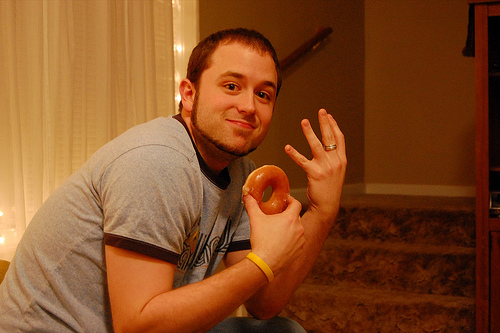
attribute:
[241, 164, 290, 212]
donut — iced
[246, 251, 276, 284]
band — yellow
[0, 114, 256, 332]
shirt — gray, grey, short sleeved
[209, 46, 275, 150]
face — smiling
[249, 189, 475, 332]
staircase — back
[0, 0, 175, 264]
curtain — white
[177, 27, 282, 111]
hair — short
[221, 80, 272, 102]
eyes — open